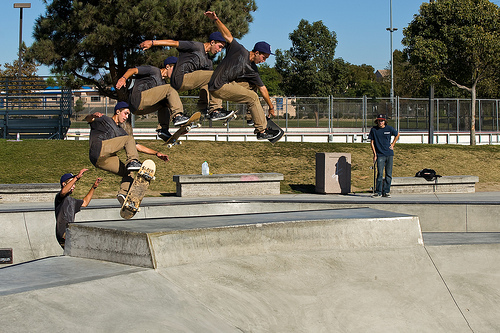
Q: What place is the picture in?
A: It is at the skate park.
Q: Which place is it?
A: It is a skate park.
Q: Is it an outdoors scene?
A: Yes, it is outdoors.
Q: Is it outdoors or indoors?
A: It is outdoors.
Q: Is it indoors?
A: No, it is outdoors.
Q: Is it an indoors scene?
A: No, it is outdoors.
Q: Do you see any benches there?
A: Yes, there is a bench.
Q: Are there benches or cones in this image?
A: Yes, there is a bench.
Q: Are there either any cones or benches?
A: Yes, there is a bench.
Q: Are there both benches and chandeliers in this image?
A: No, there is a bench but no chandeliers.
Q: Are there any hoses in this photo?
A: No, there are no hoses.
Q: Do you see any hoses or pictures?
A: No, there are no hoses or pictures.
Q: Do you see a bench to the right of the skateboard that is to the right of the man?
A: Yes, there is a bench to the right of the skateboard.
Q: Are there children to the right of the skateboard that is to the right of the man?
A: No, there is a bench to the right of the skateboard.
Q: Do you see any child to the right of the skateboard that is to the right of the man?
A: No, there is a bench to the right of the skateboard.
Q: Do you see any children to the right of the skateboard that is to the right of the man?
A: No, there is a bench to the right of the skateboard.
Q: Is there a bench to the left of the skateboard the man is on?
A: Yes, there is a bench to the left of the skateboard.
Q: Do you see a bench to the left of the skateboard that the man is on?
A: Yes, there is a bench to the left of the skateboard.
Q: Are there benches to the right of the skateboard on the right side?
A: No, the bench is to the left of the skateboard.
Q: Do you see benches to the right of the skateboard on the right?
A: No, the bench is to the left of the skateboard.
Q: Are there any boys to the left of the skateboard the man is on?
A: No, there is a bench to the left of the skateboard.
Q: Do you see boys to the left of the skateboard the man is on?
A: No, there is a bench to the left of the skateboard.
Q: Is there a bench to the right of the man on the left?
A: Yes, there is a bench to the right of the man.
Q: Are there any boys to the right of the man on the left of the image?
A: No, there is a bench to the right of the man.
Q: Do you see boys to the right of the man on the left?
A: No, there is a bench to the right of the man.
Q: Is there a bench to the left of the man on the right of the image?
A: Yes, there is a bench to the left of the man.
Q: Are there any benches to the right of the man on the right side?
A: No, the bench is to the left of the man.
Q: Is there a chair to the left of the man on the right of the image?
A: No, there is a bench to the left of the man.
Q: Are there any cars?
A: No, there are no cars.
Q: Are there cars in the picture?
A: No, there are no cars.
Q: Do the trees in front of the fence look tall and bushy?
A: Yes, the trees are tall and bushy.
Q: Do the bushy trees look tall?
A: Yes, the trees are tall.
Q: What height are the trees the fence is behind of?
A: The trees are tall.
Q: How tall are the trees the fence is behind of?
A: The trees are tall.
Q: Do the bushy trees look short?
A: No, the trees are tall.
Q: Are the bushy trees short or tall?
A: The trees are tall.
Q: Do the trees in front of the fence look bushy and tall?
A: Yes, the trees are bushy and tall.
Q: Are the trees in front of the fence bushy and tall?
A: Yes, the trees are bushy and tall.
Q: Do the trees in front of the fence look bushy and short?
A: No, the trees are bushy but tall.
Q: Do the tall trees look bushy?
A: Yes, the trees are bushy.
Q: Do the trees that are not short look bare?
A: No, the trees are bushy.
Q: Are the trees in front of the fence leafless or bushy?
A: The trees are bushy.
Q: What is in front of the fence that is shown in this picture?
A: The trees are in front of the fence.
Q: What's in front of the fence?
A: The trees are in front of the fence.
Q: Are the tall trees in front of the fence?
A: Yes, the trees are in front of the fence.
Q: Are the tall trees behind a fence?
A: No, the trees are in front of a fence.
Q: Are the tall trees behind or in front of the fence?
A: The trees are in front of the fence.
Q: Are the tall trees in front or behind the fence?
A: The trees are in front of the fence.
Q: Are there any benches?
A: Yes, there is a bench.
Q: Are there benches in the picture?
A: Yes, there is a bench.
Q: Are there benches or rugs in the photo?
A: Yes, there is a bench.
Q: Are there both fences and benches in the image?
A: Yes, there are both a bench and a fence.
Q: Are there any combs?
A: No, there are no combs.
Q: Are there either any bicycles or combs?
A: No, there are no combs or bicycles.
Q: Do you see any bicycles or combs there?
A: No, there are no combs or bicycles.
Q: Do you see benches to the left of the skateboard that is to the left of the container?
A: Yes, there is a bench to the left of the skateboard.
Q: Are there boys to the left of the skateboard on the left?
A: No, there is a bench to the left of the skateboard.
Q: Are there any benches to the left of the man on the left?
A: Yes, there is a bench to the left of the man.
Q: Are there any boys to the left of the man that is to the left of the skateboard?
A: No, there is a bench to the left of the man.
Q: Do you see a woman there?
A: No, there are no women.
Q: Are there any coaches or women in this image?
A: No, there are no women or coaches.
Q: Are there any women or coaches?
A: No, there are no women or coaches.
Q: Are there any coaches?
A: No, there are no coaches.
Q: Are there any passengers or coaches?
A: No, there are no coaches or passengers.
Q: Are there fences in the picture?
A: Yes, there is a fence.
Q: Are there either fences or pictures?
A: Yes, there is a fence.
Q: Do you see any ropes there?
A: No, there are no ropes.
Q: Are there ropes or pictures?
A: No, there are no ropes or pictures.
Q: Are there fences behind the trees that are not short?
A: Yes, there is a fence behind the trees.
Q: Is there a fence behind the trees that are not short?
A: Yes, there is a fence behind the trees.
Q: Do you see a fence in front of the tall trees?
A: No, the fence is behind the trees.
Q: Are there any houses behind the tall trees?
A: No, there is a fence behind the trees.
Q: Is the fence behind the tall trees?
A: Yes, the fence is behind the trees.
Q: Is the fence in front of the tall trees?
A: No, the fence is behind the trees.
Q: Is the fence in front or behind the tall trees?
A: The fence is behind the trees.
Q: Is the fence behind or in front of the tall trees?
A: The fence is behind the trees.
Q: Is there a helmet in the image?
A: No, there are no helmets.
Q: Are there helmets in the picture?
A: No, there are no helmets.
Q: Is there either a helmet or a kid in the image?
A: No, there are no helmets or children.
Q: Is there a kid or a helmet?
A: No, there are no helmets or children.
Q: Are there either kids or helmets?
A: No, there are no helmets or kids.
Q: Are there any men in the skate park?
A: Yes, there is a man in the skate park.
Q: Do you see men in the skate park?
A: Yes, there is a man in the skate park.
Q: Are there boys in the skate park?
A: No, there is a man in the skate park.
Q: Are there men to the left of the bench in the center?
A: Yes, there is a man to the left of the bench.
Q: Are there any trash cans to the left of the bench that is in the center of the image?
A: No, there is a man to the left of the bench.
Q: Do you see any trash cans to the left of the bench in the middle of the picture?
A: No, there is a man to the left of the bench.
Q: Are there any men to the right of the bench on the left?
A: Yes, there is a man to the right of the bench.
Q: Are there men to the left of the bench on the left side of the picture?
A: No, the man is to the right of the bench.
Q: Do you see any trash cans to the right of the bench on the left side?
A: No, there is a man to the right of the bench.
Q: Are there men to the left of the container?
A: Yes, there is a man to the left of the container.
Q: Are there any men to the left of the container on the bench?
A: Yes, there is a man to the left of the container.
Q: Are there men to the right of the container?
A: No, the man is to the left of the container.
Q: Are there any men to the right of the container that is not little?
A: No, the man is to the left of the container.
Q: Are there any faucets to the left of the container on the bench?
A: No, there is a man to the left of the container.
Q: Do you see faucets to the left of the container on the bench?
A: No, there is a man to the left of the container.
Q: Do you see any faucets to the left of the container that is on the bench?
A: No, there is a man to the left of the container.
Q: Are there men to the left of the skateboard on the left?
A: Yes, there is a man to the left of the skateboard.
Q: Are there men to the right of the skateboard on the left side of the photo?
A: No, the man is to the left of the skateboard.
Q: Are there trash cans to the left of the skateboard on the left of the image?
A: No, there is a man to the left of the skateboard.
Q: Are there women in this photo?
A: No, there are no women.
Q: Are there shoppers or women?
A: No, there are no women or shoppers.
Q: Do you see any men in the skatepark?
A: Yes, there is a man in the skatepark.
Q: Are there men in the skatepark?
A: Yes, there is a man in the skatepark.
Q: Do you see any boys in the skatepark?
A: No, there is a man in the skatepark.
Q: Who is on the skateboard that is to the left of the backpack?
A: The man is on the skateboard.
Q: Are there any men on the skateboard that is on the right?
A: Yes, there is a man on the skateboard.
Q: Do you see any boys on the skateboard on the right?
A: No, there is a man on the skateboard.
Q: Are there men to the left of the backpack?
A: Yes, there is a man to the left of the backpack.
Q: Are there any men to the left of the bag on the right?
A: Yes, there is a man to the left of the backpack.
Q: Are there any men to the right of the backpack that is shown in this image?
A: No, the man is to the left of the backpack.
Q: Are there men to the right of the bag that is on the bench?
A: No, the man is to the left of the backpack.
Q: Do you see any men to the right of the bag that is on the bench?
A: No, the man is to the left of the backpack.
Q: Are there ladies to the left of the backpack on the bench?
A: No, there is a man to the left of the backpack.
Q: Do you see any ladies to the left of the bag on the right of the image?
A: No, there is a man to the left of the backpack.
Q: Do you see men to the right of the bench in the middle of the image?
A: Yes, there is a man to the right of the bench.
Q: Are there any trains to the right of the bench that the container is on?
A: No, there is a man to the right of the bench.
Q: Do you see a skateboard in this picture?
A: Yes, there is a skateboard.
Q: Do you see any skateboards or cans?
A: Yes, there is a skateboard.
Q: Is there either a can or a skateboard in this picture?
A: Yes, there is a skateboard.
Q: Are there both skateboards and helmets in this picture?
A: No, there is a skateboard but no helmets.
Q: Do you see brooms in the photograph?
A: No, there are no brooms.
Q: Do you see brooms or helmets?
A: No, there are no brooms or helmets.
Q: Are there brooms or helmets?
A: No, there are no brooms or helmets.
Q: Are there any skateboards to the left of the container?
A: Yes, there is a skateboard to the left of the container.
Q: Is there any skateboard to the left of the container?
A: Yes, there is a skateboard to the left of the container.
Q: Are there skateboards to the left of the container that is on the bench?
A: Yes, there is a skateboard to the left of the container.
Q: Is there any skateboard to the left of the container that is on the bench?
A: Yes, there is a skateboard to the left of the container.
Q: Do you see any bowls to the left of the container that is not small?
A: No, there is a skateboard to the left of the container.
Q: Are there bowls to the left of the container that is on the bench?
A: No, there is a skateboard to the left of the container.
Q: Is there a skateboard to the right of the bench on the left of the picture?
A: Yes, there is a skateboard to the right of the bench.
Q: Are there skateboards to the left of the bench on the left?
A: No, the skateboard is to the right of the bench.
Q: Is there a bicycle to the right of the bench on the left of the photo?
A: No, there is a skateboard to the right of the bench.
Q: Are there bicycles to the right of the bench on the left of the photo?
A: No, there is a skateboard to the right of the bench.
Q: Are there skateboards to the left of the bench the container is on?
A: Yes, there is a skateboard to the left of the bench.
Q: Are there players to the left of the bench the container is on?
A: No, there is a skateboard to the left of the bench.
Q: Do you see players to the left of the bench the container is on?
A: No, there is a skateboard to the left of the bench.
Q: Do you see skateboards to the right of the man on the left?
A: Yes, there is a skateboard to the right of the man.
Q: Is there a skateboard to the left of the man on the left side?
A: No, the skateboard is to the right of the man.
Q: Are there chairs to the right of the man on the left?
A: No, there is a skateboard to the right of the man.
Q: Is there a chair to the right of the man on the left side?
A: No, there is a skateboard to the right of the man.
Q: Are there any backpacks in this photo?
A: Yes, there is a backpack.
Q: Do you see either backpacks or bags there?
A: Yes, there is a backpack.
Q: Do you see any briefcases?
A: No, there are no briefcases.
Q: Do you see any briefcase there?
A: No, there are no briefcases.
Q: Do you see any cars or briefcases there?
A: No, there are no briefcases or cars.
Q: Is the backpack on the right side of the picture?
A: Yes, the backpack is on the right of the image.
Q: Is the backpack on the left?
A: No, the backpack is on the right of the image.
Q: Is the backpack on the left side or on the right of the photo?
A: The backpack is on the right of the image.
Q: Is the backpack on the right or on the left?
A: The backpack is on the right of the image.